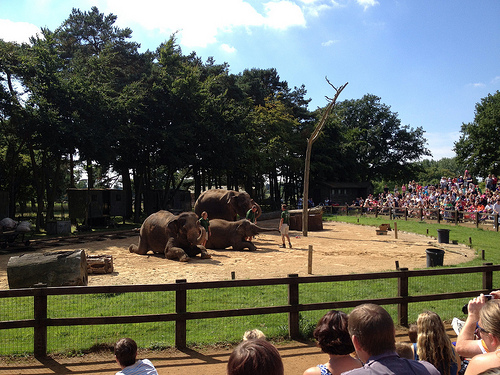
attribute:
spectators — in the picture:
[353, 178, 496, 230]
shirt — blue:
[342, 352, 444, 372]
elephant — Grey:
[203, 217, 283, 252]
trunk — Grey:
[256, 226, 280, 233]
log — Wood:
[7, 252, 94, 293]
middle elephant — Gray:
[205, 218, 281, 251]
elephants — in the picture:
[125, 185, 261, 263]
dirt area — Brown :
[0, 219, 475, 289]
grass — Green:
[5, 221, 499, 328]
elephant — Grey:
[191, 188, 251, 222]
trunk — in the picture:
[255, 222, 283, 237]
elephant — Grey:
[129, 207, 213, 261]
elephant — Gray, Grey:
[206, 217, 280, 251]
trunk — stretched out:
[256, 225, 280, 234]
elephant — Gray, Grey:
[127, 209, 212, 259]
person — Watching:
[263, 187, 329, 259]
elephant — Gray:
[124, 207, 212, 264]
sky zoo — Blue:
[326, 3, 478, 78]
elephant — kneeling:
[131, 211, 211, 263]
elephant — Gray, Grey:
[193, 187, 260, 219]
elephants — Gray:
[127, 207, 210, 263]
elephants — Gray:
[202, 216, 263, 244]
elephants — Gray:
[192, 181, 262, 219]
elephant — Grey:
[129, 202, 203, 260]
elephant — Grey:
[207, 214, 257, 253]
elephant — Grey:
[193, 185, 260, 228]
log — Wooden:
[5, 247, 89, 288]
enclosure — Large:
[2, 163, 497, 365]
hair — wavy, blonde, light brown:
[416, 310, 455, 373]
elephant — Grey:
[159, 210, 214, 255]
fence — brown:
[0, 252, 489, 368]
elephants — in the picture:
[120, 203, 281, 264]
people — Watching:
[343, 168, 499, 225]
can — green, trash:
[416, 241, 450, 274]